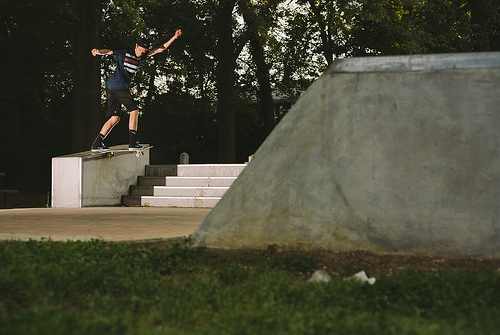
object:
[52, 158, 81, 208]
wall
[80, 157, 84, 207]
edge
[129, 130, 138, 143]
sock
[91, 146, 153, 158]
skateboard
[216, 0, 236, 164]
tree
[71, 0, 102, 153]
trunk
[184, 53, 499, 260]
concrete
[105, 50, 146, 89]
shirt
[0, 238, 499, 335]
grass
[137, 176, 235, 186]
stairs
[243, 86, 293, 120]
building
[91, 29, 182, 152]
man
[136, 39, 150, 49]
hat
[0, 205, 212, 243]
pavement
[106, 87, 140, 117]
shorts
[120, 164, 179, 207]
shadows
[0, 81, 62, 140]
air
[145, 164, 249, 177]
set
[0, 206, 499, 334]
ground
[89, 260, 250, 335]
patch